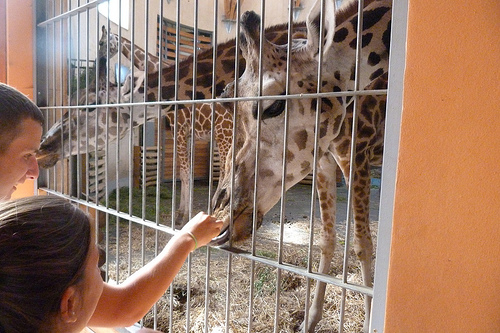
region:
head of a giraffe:
[213, 0, 370, 331]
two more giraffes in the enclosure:
[45, 26, 229, 186]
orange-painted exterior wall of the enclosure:
[409, 1, 496, 328]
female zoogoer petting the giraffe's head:
[3, 196, 228, 331]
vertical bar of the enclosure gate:
[49, 83, 385, 118]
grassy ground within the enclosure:
[184, 272, 299, 332]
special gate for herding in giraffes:
[157, 15, 213, 187]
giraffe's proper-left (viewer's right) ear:
[303, 0, 343, 62]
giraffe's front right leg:
[300, 168, 340, 332]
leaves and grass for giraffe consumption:
[69, 61, 108, 93]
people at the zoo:
[0, 76, 247, 331]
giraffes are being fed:
[31, 20, 333, 245]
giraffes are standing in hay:
[180, 257, 360, 331]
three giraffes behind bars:
[30, 5, 370, 290]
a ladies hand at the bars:
[165, 200, 236, 262]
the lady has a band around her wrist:
[172, 223, 199, 251]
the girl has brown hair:
[2, 191, 94, 328]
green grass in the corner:
[104, 178, 174, 218]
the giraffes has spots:
[355, 91, 385, 194]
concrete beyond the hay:
[283, 185, 309, 234]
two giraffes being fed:
[58, 71, 368, 257]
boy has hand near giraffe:
[130, 195, 249, 299]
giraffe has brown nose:
[209, 165, 257, 250]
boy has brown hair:
[1, 77, 46, 123]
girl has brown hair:
[0, 199, 65, 329]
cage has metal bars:
[57, 15, 322, 268]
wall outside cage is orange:
[429, 65, 496, 296]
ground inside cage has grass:
[158, 214, 318, 317]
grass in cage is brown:
[210, 250, 328, 332]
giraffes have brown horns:
[226, 26, 280, 76]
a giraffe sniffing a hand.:
[183, 0, 359, 277]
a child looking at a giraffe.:
[2, 192, 116, 329]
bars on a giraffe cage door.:
[41, 0, 391, 332]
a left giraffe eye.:
[246, 77, 298, 125]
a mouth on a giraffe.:
[177, 183, 269, 255]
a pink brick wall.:
[380, 8, 497, 332]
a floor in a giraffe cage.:
[74, 214, 381, 331]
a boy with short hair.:
[5, 101, 62, 193]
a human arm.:
[113, 157, 242, 319]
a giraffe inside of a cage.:
[68, 23, 357, 271]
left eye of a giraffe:
[256, 93, 289, 118]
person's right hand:
[185, 207, 230, 242]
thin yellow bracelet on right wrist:
[178, 219, 199, 253]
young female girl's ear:
[60, 286, 80, 326]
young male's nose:
[26, 152, 38, 179]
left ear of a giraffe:
[304, 0, 337, 62]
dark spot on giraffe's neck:
[185, 71, 220, 89]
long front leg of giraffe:
[166, 115, 193, 232]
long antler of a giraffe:
[240, 10, 267, 64]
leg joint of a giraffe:
[316, 227, 338, 252]